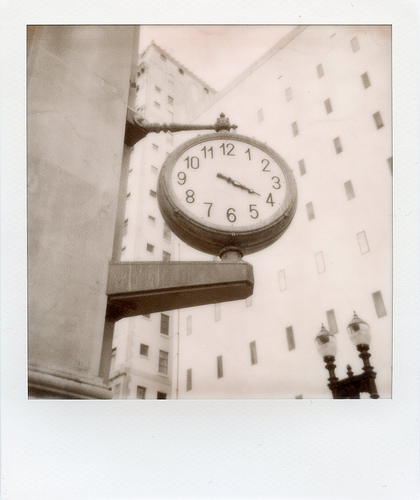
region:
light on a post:
[311, 315, 336, 376]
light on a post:
[344, 309, 377, 367]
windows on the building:
[279, 53, 341, 135]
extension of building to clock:
[131, 102, 230, 137]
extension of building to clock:
[113, 240, 254, 308]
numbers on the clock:
[215, 141, 242, 223]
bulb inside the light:
[349, 329, 367, 341]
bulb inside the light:
[318, 339, 332, 350]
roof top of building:
[144, 45, 174, 53]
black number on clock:
[221, 138, 236, 155]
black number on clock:
[244, 146, 253, 162]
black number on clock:
[259, 154, 272, 174]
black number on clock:
[271, 174, 283, 190]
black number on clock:
[263, 191, 276, 207]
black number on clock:
[246, 198, 260, 219]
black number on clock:
[225, 205, 238, 223]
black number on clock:
[200, 199, 215, 219]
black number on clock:
[183, 186, 196, 204]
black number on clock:
[174, 171, 189, 187]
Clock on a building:
[156, 128, 296, 254]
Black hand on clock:
[218, 168, 264, 198]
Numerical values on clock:
[177, 139, 283, 222]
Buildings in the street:
[113, 24, 399, 396]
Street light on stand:
[312, 321, 344, 380]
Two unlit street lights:
[314, 312, 377, 393]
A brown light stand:
[323, 341, 378, 399]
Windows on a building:
[183, 294, 388, 393]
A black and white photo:
[26, 25, 392, 399]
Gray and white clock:
[158, 113, 297, 260]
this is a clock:
[139, 89, 367, 358]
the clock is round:
[128, 93, 313, 276]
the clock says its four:
[155, 96, 353, 274]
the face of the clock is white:
[158, 107, 308, 282]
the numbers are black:
[146, 100, 333, 285]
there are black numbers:
[147, 123, 305, 259]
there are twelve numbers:
[143, 91, 327, 291]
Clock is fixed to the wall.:
[165, 126, 291, 249]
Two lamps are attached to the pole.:
[312, 303, 375, 369]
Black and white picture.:
[27, 21, 396, 411]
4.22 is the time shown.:
[162, 132, 297, 243]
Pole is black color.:
[318, 345, 378, 390]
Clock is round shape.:
[156, 126, 306, 249]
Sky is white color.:
[162, 30, 273, 69]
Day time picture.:
[25, 25, 397, 403]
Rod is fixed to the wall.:
[62, 244, 200, 318]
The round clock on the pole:
[157, 134, 294, 257]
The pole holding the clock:
[134, 114, 239, 130]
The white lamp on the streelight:
[314, 322, 339, 361]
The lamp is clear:
[345, 309, 372, 350]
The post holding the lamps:
[322, 344, 380, 404]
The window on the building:
[341, 177, 356, 202]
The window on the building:
[157, 348, 169, 374]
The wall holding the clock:
[28, 27, 140, 402]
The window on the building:
[372, 112, 387, 131]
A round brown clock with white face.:
[154, 130, 299, 259]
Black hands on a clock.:
[215, 172, 260, 196]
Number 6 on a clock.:
[225, 207, 235, 222]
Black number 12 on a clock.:
[220, 141, 235, 156]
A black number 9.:
[178, 171, 187, 185]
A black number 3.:
[270, 174, 281, 190]